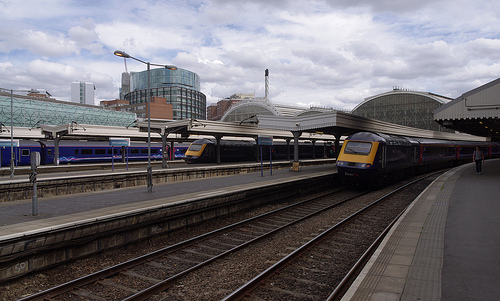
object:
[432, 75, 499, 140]
building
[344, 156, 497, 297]
platform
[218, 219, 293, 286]
dark gravel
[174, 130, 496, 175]
trains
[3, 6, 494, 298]
photo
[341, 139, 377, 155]
windshield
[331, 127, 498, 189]
train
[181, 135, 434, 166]
train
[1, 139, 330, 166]
train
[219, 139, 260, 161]
left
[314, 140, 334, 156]
left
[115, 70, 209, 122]
glass building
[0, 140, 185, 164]
blue train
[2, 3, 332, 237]
background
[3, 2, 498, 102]
cloudy sky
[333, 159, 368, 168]
headlight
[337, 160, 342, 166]
light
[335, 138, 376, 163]
front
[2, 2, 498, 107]
sky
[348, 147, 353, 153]
wiper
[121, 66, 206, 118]
building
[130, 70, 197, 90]
glass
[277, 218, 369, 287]
tracks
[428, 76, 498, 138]
awning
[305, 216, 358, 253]
gravel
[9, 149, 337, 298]
tracks